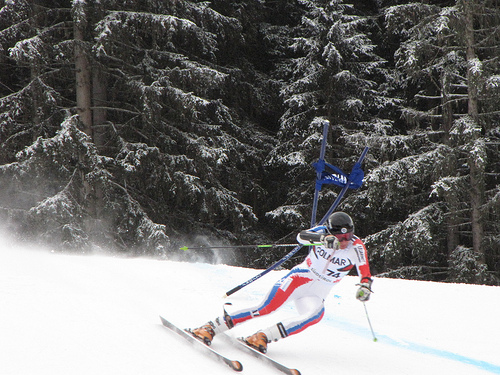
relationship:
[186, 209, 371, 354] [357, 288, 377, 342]
skier holds ski poles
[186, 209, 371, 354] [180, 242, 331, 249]
skier holds ski poles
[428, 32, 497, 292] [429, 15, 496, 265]
trunk on right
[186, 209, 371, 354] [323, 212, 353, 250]
skier wearing a helmet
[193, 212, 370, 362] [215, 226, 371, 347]
man wears clothing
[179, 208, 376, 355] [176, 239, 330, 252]
man has ski poles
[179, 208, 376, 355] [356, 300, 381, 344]
man has ski pole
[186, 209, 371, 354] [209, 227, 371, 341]
skier has outfit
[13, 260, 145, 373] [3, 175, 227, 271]
snow has powder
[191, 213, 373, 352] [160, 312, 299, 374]
person wears skis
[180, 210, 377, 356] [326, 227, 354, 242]
person wears goggles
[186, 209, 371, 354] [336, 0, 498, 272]
skier close to tree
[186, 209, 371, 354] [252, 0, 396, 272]
skier close to tree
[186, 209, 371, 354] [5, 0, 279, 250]
skier close to tree